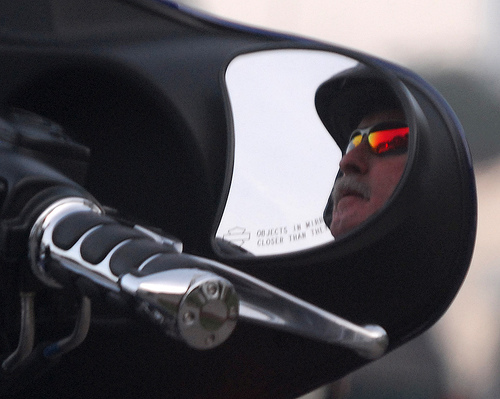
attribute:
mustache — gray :
[324, 177, 371, 210]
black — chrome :
[83, 237, 105, 249]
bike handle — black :
[12, 186, 389, 358]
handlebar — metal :
[24, 196, 389, 358]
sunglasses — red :
[329, 119, 411, 163]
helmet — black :
[305, 68, 434, 110]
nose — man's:
[332, 134, 387, 187]